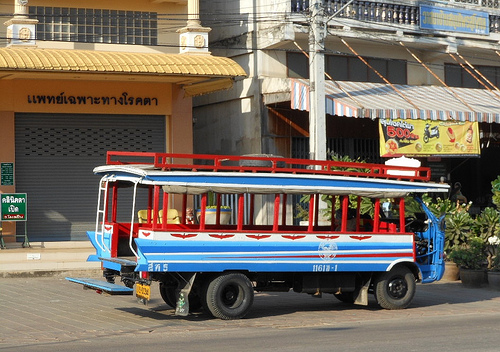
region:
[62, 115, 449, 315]
a bus is in the raod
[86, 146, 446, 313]
the bus is red, blue and white in color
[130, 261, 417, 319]
the wheels to the bus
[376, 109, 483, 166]
an advertisement banner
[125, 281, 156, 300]
the license plate is yellow in color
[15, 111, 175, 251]
a garage door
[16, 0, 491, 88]
several power lines are above the road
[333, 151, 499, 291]
many plants are outside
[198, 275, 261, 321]
the tire is black in color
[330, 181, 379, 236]
a person is on the bus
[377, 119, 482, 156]
A hanging yellow banner.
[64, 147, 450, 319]
A red white and blue bus.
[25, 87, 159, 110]
Black lettering on a building.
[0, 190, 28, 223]
A green and white sign.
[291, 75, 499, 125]
A red white and blue awning.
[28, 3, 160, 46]
A large multipane window.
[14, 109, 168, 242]
A large gray entry door.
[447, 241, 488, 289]
A green potted plant.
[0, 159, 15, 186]
A small green and white sign.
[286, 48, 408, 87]
A long multipane window.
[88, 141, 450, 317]
a truck parked in the corner of the road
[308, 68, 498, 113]
sheet in front of the building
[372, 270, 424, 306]
black wheel of the truck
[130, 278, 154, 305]
yellow color number board of the truck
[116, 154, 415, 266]
red and blue color coated truck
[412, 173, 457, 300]
front portion of the truck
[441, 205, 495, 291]
plants in the pot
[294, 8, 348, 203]
electric post with electric wire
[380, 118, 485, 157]
advertisement banner hanging in the wall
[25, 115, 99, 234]
grey color shutter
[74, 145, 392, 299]
blue and white bus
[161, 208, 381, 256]
red animals on bus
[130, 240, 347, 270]
white letters on bus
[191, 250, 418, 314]
black wheels on bus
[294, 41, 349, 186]
white pole behind bus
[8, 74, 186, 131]
black and yellow sign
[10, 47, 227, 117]
yellow awning over sign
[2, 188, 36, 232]
green and white sign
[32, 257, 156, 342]
pavement is light grey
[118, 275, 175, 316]
black and yellow license plate on bus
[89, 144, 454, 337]
this is a bus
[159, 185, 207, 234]
a window on the bus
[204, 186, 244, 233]
a window on the bus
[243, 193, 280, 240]
a window on the bus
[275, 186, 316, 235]
a window on the bus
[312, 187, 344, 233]
a window on the bus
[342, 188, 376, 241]
a window on the bus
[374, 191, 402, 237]
a window on the bus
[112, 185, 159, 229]
a window on the bus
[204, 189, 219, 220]
a window on the bus